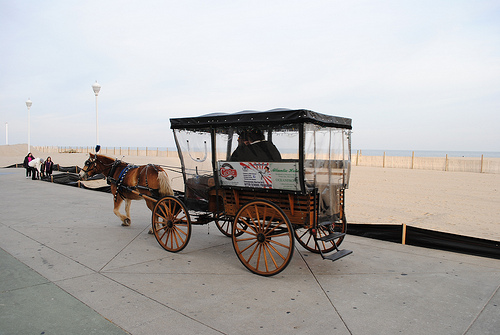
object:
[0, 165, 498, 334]
floor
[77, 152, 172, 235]
horse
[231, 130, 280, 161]
person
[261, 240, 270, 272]
spokes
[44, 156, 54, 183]
person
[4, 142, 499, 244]
sand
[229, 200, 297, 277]
wheel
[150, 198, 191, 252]
wheel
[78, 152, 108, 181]
head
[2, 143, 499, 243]
beach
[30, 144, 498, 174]
fence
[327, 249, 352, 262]
steps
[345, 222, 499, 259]
barrier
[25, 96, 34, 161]
lights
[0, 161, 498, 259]
fabric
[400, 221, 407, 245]
post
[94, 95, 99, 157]
lamp post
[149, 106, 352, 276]
carriage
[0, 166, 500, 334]
pavement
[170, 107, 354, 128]
roof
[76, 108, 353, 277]
horse and buggy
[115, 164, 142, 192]
harness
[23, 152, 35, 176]
people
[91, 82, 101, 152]
streetlight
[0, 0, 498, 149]
sky